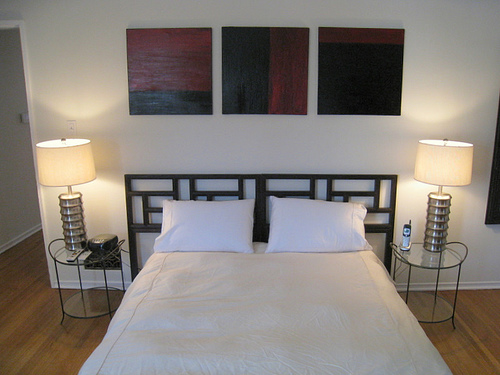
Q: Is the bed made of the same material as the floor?
A: Yes, both the bed and the floor are made of wood.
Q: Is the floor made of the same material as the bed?
A: Yes, both the floor and the bed are made of wood.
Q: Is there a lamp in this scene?
A: Yes, there is a lamp.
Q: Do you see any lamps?
A: Yes, there is a lamp.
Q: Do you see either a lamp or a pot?
A: Yes, there is a lamp.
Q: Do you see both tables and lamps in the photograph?
A: Yes, there are both a lamp and a table.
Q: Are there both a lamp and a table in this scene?
A: Yes, there are both a lamp and a table.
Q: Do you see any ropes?
A: No, there are no ropes.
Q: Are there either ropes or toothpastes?
A: No, there are no ropes or toothpastes.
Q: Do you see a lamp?
A: Yes, there is a lamp.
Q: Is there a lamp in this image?
A: Yes, there is a lamp.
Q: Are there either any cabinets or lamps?
A: Yes, there is a lamp.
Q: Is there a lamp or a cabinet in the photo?
A: Yes, there is a lamp.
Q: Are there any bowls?
A: No, there are no bowls.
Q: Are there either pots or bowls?
A: No, there are no bowls or pots.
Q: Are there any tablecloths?
A: No, there are no tablecloths.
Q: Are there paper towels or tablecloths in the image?
A: No, there are no tablecloths or paper towels.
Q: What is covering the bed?
A: The sheet is covering the bed.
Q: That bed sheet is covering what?
A: The bed sheet is covering the bed.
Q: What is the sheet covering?
A: The bed sheet is covering the bed.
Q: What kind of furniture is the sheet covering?
A: The bed sheet is covering the bed.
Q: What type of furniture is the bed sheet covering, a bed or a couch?
A: The bed sheet is covering a bed.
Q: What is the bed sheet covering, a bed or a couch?
A: The bed sheet is covering a bed.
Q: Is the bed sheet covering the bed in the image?
A: Yes, the bed sheet is covering the bed.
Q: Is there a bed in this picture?
A: Yes, there is a bed.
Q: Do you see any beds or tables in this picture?
A: Yes, there is a bed.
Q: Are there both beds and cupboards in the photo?
A: No, there is a bed but no cupboards.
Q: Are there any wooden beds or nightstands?
A: Yes, there is a wood bed.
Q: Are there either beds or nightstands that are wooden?
A: Yes, the bed is wooden.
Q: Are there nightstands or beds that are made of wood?
A: Yes, the bed is made of wood.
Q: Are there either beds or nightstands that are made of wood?
A: Yes, the bed is made of wood.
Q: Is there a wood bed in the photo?
A: Yes, there is a bed that is made of wood.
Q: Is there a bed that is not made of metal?
A: Yes, there is a bed that is made of wood.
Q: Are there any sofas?
A: No, there are no sofas.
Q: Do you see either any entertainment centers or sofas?
A: No, there are no sofas or entertainment centers.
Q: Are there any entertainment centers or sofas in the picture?
A: No, there are no sofas or entertainment centers.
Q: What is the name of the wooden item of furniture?
A: The piece of furniture is a bed.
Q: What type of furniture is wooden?
A: The furniture is a bed.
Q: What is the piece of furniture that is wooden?
A: The piece of furniture is a bed.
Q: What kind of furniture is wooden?
A: The furniture is a bed.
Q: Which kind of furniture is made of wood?
A: The furniture is a bed.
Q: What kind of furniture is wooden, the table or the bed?
A: The bed is wooden.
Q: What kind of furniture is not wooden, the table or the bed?
A: The table is not wooden.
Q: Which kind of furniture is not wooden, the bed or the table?
A: The table is not wooden.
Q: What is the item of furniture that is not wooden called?
A: The piece of furniture is a table.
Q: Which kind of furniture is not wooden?
A: The furniture is a table.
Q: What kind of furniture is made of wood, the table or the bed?
A: The bed is made of wood.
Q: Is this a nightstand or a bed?
A: This is a bed.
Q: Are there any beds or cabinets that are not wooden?
A: No, there is a bed but it is wooden.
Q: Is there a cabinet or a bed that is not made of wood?
A: No, there is a bed but it is made of wood.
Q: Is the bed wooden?
A: Yes, the bed is wooden.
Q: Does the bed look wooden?
A: Yes, the bed is wooden.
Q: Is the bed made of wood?
A: Yes, the bed is made of wood.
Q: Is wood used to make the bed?
A: Yes, the bed is made of wood.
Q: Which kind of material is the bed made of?
A: The bed is made of wood.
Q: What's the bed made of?
A: The bed is made of wood.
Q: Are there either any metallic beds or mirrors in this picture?
A: No, there is a bed but it is wooden.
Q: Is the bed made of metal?
A: No, the bed is made of wood.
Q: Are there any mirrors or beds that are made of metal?
A: No, there is a bed but it is made of wood.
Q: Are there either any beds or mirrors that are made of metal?
A: No, there is a bed but it is made of wood.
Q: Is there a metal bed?
A: No, there is a bed but it is made of wood.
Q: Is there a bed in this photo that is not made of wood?
A: No, there is a bed but it is made of wood.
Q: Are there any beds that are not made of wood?
A: No, there is a bed but it is made of wood.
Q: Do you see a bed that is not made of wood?
A: No, there is a bed but it is made of wood.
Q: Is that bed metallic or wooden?
A: The bed is wooden.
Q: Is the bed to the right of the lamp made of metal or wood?
A: The bed is made of wood.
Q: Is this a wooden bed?
A: Yes, this is a wooden bed.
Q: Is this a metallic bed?
A: No, this is a wooden bed.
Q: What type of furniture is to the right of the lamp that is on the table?
A: The piece of furniture is a bed.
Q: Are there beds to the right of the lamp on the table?
A: Yes, there is a bed to the right of the lamp.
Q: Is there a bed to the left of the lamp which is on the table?
A: No, the bed is to the right of the lamp.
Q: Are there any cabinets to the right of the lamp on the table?
A: No, there is a bed to the right of the lamp.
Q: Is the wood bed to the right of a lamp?
A: Yes, the bed is to the right of a lamp.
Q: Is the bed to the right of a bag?
A: No, the bed is to the right of a lamp.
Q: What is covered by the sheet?
A: The bed is covered by the bed sheet.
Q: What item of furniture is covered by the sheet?
A: The piece of furniture is a bed.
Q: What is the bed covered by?
A: The bed is covered by the sheet.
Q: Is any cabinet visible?
A: No, there are no cabinets.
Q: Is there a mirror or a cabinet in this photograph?
A: No, there are no cabinets or mirrors.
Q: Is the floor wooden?
A: Yes, the floor is wooden.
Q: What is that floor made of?
A: The floor is made of wood.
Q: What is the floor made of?
A: The floor is made of wood.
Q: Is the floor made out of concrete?
A: No, the floor is made of wood.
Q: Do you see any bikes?
A: No, there are no bikes.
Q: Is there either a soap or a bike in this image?
A: No, there are no bikes or soaps.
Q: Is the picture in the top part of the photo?
A: Yes, the picture is in the top of the image.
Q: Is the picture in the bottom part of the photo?
A: No, the picture is in the top of the image.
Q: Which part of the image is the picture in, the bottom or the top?
A: The picture is in the top of the image.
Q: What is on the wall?
A: The picture is on the wall.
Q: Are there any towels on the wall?
A: No, there is a picture on the wall.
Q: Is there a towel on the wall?
A: No, there is a picture on the wall.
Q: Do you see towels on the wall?
A: No, there is a picture on the wall.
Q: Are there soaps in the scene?
A: No, there are no soaps.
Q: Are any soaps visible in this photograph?
A: No, there are no soaps.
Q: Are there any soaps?
A: No, there are no soaps.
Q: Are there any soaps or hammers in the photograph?
A: No, there are no soaps or hammers.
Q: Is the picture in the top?
A: Yes, the picture is in the top of the image.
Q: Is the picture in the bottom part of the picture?
A: No, the picture is in the top of the image.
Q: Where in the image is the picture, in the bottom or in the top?
A: The picture is in the top of the image.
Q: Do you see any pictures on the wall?
A: Yes, there is a picture on the wall.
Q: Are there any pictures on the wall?
A: Yes, there is a picture on the wall.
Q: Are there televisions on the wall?
A: No, there is a picture on the wall.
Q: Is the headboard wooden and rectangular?
A: Yes, the headboard is wooden and rectangular.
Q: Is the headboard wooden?
A: Yes, the headboard is wooden.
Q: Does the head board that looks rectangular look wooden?
A: Yes, the headboard is wooden.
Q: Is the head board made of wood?
A: Yes, the head board is made of wood.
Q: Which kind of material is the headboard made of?
A: The headboard is made of wood.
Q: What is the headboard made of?
A: The headboard is made of wood.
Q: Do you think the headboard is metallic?
A: No, the headboard is wooden.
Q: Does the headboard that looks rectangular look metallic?
A: No, the head board is wooden.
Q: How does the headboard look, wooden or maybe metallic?
A: The headboard is wooden.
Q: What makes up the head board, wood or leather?
A: The head board is made of wood.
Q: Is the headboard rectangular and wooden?
A: Yes, the headboard is rectangular and wooden.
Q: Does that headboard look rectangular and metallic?
A: No, the headboard is rectangular but wooden.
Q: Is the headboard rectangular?
A: Yes, the headboard is rectangular.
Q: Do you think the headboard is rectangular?
A: Yes, the headboard is rectangular.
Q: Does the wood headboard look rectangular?
A: Yes, the headboard is rectangular.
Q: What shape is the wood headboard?
A: The head board is rectangular.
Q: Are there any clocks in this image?
A: Yes, there is a clock.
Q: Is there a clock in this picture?
A: Yes, there is a clock.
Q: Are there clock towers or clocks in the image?
A: Yes, there is a clock.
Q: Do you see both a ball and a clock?
A: No, there is a clock but no balls.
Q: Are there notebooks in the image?
A: No, there are no notebooks.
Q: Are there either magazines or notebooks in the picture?
A: No, there are no notebooks or magazines.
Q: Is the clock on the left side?
A: Yes, the clock is on the left of the image.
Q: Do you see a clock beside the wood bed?
A: Yes, there is a clock beside the bed.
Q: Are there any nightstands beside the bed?
A: No, there is a clock beside the bed.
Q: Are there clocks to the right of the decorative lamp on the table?
A: Yes, there is a clock to the right of the lamp.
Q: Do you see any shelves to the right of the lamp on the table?
A: No, there is a clock to the right of the lamp.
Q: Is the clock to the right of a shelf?
A: No, the clock is to the right of a lamp.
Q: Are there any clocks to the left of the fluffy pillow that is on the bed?
A: Yes, there is a clock to the left of the pillow.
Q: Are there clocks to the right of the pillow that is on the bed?
A: No, the clock is to the left of the pillow.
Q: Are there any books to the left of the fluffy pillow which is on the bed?
A: No, there is a clock to the left of the pillow.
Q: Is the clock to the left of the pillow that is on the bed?
A: Yes, the clock is to the left of the pillow.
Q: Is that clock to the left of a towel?
A: No, the clock is to the left of the pillow.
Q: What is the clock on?
A: The clock is on the table.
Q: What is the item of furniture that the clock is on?
A: The piece of furniture is a table.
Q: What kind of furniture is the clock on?
A: The clock is on the table.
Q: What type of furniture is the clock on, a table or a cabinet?
A: The clock is on a table.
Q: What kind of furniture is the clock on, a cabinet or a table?
A: The clock is on a table.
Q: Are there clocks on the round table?
A: Yes, there is a clock on the table.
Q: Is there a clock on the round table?
A: Yes, there is a clock on the table.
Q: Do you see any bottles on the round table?
A: No, there is a clock on the table.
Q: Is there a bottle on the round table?
A: No, there is a clock on the table.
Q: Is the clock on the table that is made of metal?
A: Yes, the clock is on the table.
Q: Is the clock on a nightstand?
A: No, the clock is on the table.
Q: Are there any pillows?
A: Yes, there is a pillow.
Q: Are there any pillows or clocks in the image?
A: Yes, there is a pillow.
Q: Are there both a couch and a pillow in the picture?
A: No, there is a pillow but no couches.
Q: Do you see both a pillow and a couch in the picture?
A: No, there is a pillow but no couches.